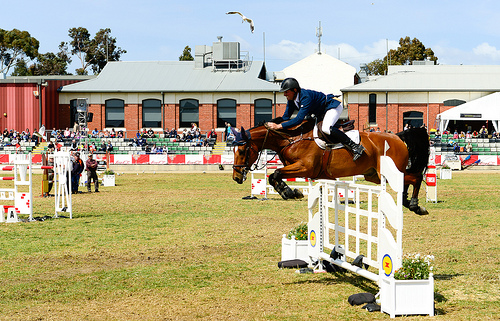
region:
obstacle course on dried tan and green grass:
[7, 152, 492, 314]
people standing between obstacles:
[40, 142, 100, 189]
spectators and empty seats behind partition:
[1, 125, 231, 150]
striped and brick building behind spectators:
[5, 41, 280, 132]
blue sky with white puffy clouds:
[0, 5, 495, 72]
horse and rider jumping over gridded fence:
[212, 75, 412, 201]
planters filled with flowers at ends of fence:
[276, 220, 436, 312]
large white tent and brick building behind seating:
[426, 65, 496, 165]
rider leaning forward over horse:
[220, 75, 367, 185]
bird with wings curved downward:
[218, 6, 263, 36]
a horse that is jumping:
[169, 76, 486, 318]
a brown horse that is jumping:
[191, 69, 403, 246]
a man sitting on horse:
[189, 70, 437, 251]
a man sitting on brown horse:
[174, 81, 451, 314]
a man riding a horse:
[250, 86, 410, 213]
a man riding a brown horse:
[212, 68, 484, 247]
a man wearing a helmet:
[257, 41, 391, 206]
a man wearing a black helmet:
[239, 78, 349, 148]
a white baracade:
[293, 123, 424, 302]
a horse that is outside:
[279, 91, 478, 283]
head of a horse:
[220, 122, 259, 184]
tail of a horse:
[398, 105, 432, 157]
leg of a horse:
[386, 178, 443, 213]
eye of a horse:
[226, 147, 260, 160]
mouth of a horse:
[228, 165, 243, 183]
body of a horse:
[295, 117, 416, 191]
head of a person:
[268, 71, 310, 99]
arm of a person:
[276, 110, 313, 129]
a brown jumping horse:
[233, 78, 429, 218]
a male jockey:
[267, 78, 365, 160]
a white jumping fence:
[276, 148, 436, 316]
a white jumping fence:
[0, 153, 36, 223]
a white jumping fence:
[245, 155, 306, 200]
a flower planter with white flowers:
[383, 250, 434, 316]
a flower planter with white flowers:
[280, 218, 310, 268]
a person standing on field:
[82, 152, 97, 192]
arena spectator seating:
[0, 130, 495, 166]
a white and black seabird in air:
[226, 10, 254, 30]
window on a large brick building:
[251, 97, 274, 127]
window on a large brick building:
[217, 96, 239, 130]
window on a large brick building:
[180, 96, 200, 128]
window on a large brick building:
[141, 97, 163, 130]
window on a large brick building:
[104, 94, 128, 131]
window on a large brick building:
[401, 108, 424, 129]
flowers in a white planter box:
[375, 250, 440, 318]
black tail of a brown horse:
[394, 125, 433, 187]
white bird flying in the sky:
[220, 7, 259, 37]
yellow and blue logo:
[378, 249, 393, 278]